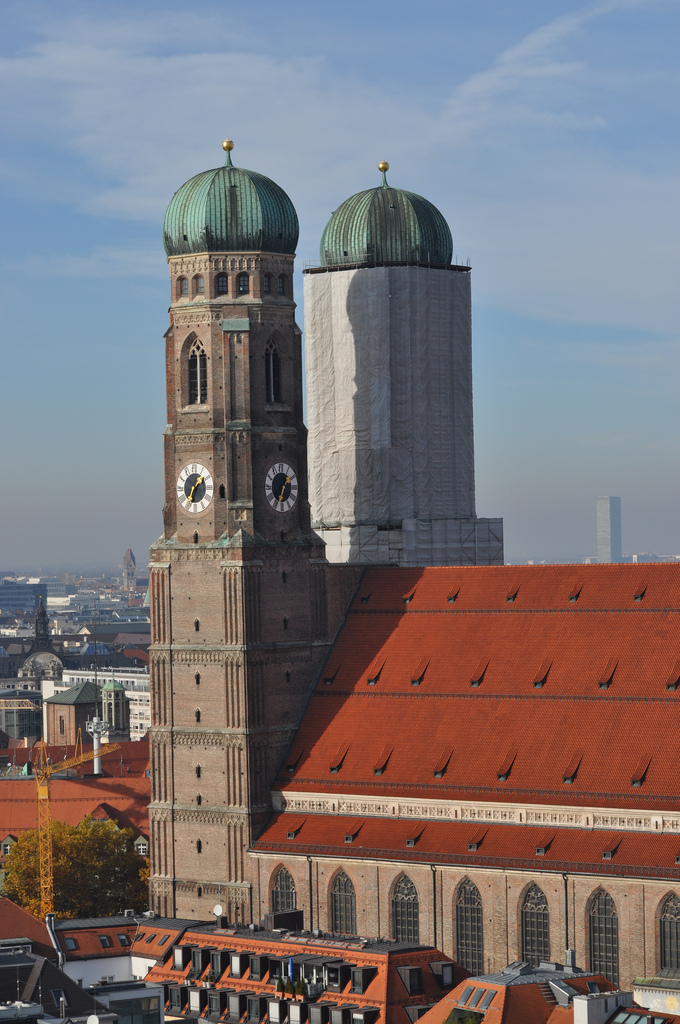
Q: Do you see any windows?
A: Yes, there is a window.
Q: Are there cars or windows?
A: Yes, there is a window.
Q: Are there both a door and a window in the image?
A: No, there is a window but no doors.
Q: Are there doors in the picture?
A: No, there are no doors.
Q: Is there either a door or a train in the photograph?
A: No, there are no doors or trains.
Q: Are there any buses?
A: No, there are no buses.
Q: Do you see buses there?
A: No, there are no buses.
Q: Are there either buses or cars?
A: No, there are no buses or cars.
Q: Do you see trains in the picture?
A: No, there are no trains.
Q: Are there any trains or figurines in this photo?
A: No, there are no trains or figurines.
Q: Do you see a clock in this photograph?
A: Yes, there is a clock.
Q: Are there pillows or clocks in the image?
A: Yes, there is a clock.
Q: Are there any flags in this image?
A: No, there are no flags.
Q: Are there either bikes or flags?
A: No, there are no flags or bikes.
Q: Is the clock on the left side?
A: Yes, the clock is on the left of the image.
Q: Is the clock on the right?
A: No, the clock is on the left of the image.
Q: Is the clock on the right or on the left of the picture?
A: The clock is on the left of the image.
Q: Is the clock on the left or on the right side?
A: The clock is on the left of the image.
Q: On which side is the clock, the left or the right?
A: The clock is on the left of the image.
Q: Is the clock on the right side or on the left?
A: The clock is on the left of the image.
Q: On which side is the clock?
A: The clock is on the left of the image.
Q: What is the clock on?
A: The clock is on the building.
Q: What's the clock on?
A: The clock is on the building.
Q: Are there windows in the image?
A: Yes, there is a window.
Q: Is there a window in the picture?
A: Yes, there is a window.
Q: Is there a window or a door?
A: Yes, there is a window.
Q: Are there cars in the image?
A: No, there are no cars.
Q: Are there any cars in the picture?
A: No, there are no cars.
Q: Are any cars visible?
A: No, there are no cars.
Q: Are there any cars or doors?
A: No, there are no cars or doors.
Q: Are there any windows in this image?
A: Yes, there is a window.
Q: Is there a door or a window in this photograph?
A: Yes, there is a window.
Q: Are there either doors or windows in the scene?
A: Yes, there is a window.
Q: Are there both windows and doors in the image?
A: No, there is a window but no doors.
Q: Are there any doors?
A: No, there are no doors.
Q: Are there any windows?
A: Yes, there is a window.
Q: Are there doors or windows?
A: Yes, there is a window.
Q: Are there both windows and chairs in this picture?
A: No, there is a window but no chairs.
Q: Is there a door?
A: No, there are no doors.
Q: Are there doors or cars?
A: No, there are no doors or cars.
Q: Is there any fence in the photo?
A: No, there are no fences.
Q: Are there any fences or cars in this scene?
A: No, there are no fences or cars.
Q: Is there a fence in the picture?
A: No, there are no fences.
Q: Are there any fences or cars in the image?
A: No, there are no fences or cars.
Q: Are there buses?
A: No, there are no buses.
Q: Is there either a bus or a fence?
A: No, there are no buses or fences.